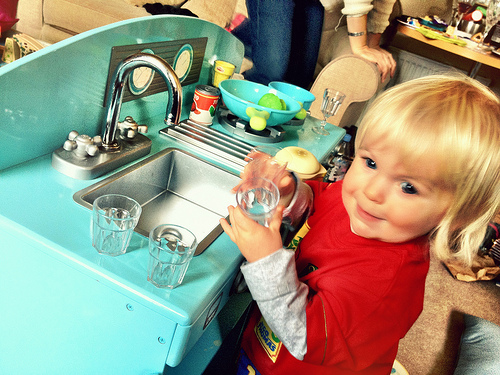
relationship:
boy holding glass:
[229, 68, 497, 371] [230, 175, 281, 224]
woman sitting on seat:
[227, 0, 403, 93] [304, 0, 403, 124]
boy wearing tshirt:
[229, 68, 497, 371] [243, 177, 432, 374]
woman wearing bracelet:
[227, 0, 403, 93] [346, 30, 369, 39]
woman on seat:
[227, 0, 403, 93] [304, 0, 403, 124]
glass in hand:
[230, 175, 281, 224] [218, 195, 284, 254]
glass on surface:
[149, 224, 195, 286] [0, 73, 347, 318]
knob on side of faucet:
[59, 125, 104, 161] [106, 52, 184, 160]